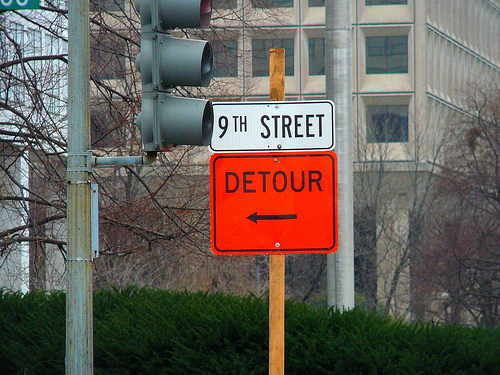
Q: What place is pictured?
A: It is a city.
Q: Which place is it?
A: It is a city.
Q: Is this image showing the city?
A: Yes, it is showing the city.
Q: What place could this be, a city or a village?
A: It is a city.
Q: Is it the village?
A: No, it is the city.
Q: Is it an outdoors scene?
A: Yes, it is outdoors.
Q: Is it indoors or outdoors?
A: It is outdoors.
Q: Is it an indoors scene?
A: No, it is outdoors.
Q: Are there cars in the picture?
A: No, there are no cars.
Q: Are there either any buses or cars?
A: No, there are no cars or buses.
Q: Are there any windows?
A: Yes, there is a window.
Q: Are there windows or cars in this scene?
A: Yes, there is a window.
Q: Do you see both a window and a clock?
A: No, there is a window but no clocks.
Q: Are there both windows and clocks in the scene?
A: No, there is a window but no clocks.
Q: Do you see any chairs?
A: No, there are no chairs.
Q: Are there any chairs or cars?
A: No, there are no chairs or cars.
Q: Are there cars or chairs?
A: No, there are no chairs or cars.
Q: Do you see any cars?
A: No, there are no cars.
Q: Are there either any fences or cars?
A: No, there are no cars or fences.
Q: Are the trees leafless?
A: Yes, the trees are leafless.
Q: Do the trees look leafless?
A: Yes, the trees are leafless.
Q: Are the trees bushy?
A: No, the trees are leafless.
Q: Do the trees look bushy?
A: No, the trees are leafless.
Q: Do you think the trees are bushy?
A: No, the trees are leafless.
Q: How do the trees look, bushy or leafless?
A: The trees are leafless.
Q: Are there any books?
A: No, there are no books.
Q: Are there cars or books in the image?
A: No, there are no books or cars.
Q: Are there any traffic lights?
A: Yes, there is a traffic light.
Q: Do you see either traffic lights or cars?
A: Yes, there is a traffic light.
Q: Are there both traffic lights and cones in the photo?
A: No, there is a traffic light but no cones.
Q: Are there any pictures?
A: No, there are no pictures.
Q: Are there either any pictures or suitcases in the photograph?
A: No, there are no pictures or suitcases.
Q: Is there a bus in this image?
A: No, there are no buses.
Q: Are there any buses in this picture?
A: No, there are no buses.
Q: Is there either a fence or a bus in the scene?
A: No, there are no buses or fences.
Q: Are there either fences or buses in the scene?
A: No, there are no buses or fences.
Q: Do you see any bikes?
A: No, there are no bikes.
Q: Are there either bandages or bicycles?
A: No, there are no bicycles or bandages.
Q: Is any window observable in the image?
A: Yes, there is a window.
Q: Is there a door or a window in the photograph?
A: Yes, there is a window.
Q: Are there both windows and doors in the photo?
A: No, there is a window but no doors.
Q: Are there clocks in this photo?
A: No, there are no clocks.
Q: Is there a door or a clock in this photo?
A: No, there are no clocks or doors.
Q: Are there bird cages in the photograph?
A: No, there are no bird cages.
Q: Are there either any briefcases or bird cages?
A: No, there are no bird cages or briefcases.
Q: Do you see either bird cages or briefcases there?
A: No, there are no bird cages or briefcases.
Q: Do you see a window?
A: Yes, there is a window.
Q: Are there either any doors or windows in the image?
A: Yes, there is a window.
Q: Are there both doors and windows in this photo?
A: No, there is a window but no doors.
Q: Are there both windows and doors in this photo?
A: No, there is a window but no doors.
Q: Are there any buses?
A: No, there are no buses.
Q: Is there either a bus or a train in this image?
A: No, there are no buses or trains.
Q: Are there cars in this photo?
A: No, there are no cars.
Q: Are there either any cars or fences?
A: No, there are no cars or fences.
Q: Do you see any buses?
A: No, there are no buses.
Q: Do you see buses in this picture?
A: No, there are no buses.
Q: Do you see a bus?
A: No, there are no buses.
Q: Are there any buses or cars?
A: No, there are no buses or cars.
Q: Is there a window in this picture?
A: Yes, there is a window.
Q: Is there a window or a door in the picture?
A: Yes, there is a window.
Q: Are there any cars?
A: No, there are no cars.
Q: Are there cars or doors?
A: No, there are no cars or doors.